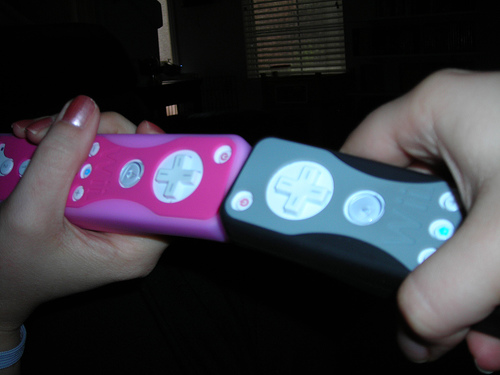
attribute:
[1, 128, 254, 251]
controller — pink, two tone, wii, touching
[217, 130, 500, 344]
controller — blue, two tone, grey, black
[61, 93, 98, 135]
fingernail — painted, pink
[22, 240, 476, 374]
space — black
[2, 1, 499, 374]
room — dark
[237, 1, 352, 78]
blind — open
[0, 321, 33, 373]
bracelet — white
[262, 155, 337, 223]
button — cross shaped, white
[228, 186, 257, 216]
button — white, red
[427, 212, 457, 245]
button — green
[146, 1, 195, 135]
doorway — light